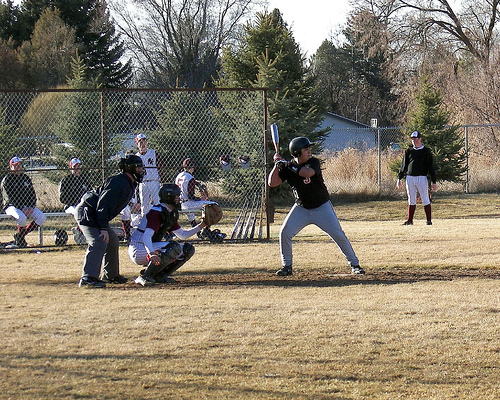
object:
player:
[266, 134, 366, 277]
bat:
[270, 123, 283, 162]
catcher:
[127, 182, 222, 287]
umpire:
[72, 154, 146, 289]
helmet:
[118, 155, 147, 184]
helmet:
[288, 136, 315, 156]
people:
[1, 130, 219, 289]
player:
[136, 132, 161, 217]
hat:
[135, 132, 149, 141]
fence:
[0, 86, 270, 252]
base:
[323, 271, 367, 278]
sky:
[1, 1, 498, 88]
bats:
[257, 186, 266, 241]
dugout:
[1, 198, 212, 246]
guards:
[129, 182, 216, 282]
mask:
[159, 181, 183, 213]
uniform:
[397, 145, 437, 225]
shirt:
[274, 155, 330, 210]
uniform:
[127, 204, 201, 280]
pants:
[279, 199, 361, 266]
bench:
[0, 210, 205, 244]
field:
[3, 195, 499, 399]